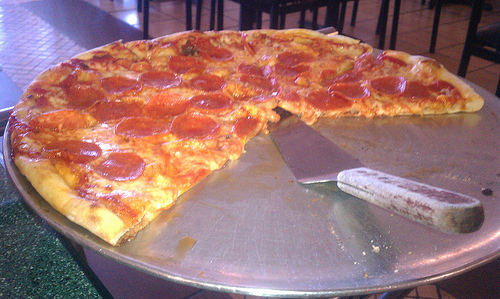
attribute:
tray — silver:
[2, 11, 498, 290]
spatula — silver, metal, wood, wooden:
[269, 109, 488, 241]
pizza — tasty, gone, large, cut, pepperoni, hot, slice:
[25, 43, 481, 216]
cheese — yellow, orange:
[113, 54, 417, 113]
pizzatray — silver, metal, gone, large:
[129, 121, 496, 285]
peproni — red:
[181, 55, 299, 75]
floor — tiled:
[22, 18, 125, 29]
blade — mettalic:
[273, 135, 353, 157]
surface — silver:
[220, 219, 373, 257]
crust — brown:
[443, 73, 484, 103]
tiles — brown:
[35, 14, 125, 39]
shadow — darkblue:
[61, 15, 124, 31]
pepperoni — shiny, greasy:
[221, 54, 373, 94]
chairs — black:
[270, 8, 479, 32]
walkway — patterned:
[29, 24, 85, 43]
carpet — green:
[74, 12, 148, 41]